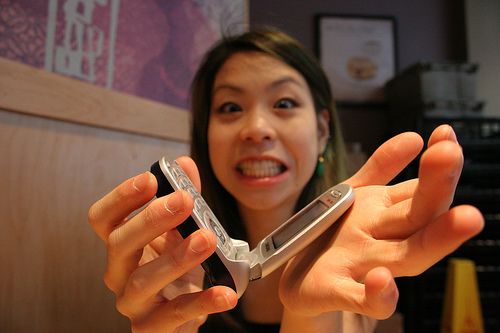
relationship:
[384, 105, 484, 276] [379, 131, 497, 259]
finger on woman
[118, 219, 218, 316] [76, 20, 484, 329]
bare finger on woman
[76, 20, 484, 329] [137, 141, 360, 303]
woman holding cell phone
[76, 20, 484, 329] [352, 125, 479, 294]
woman has hand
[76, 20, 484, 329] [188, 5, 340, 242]
woman with hair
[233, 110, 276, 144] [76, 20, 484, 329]
nose of a woman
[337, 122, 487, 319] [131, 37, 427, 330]
finger on woman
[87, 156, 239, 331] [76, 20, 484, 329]
bare finger on woman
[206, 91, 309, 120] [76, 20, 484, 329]
eyes on woman